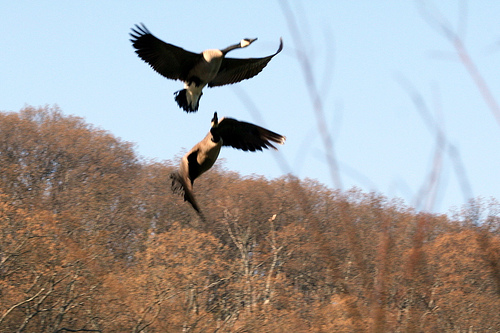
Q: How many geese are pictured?
A: 2.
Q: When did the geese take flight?
A: Morning.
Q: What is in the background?
A: Forest.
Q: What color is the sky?
A: Blue.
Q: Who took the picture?
A: Photographer.